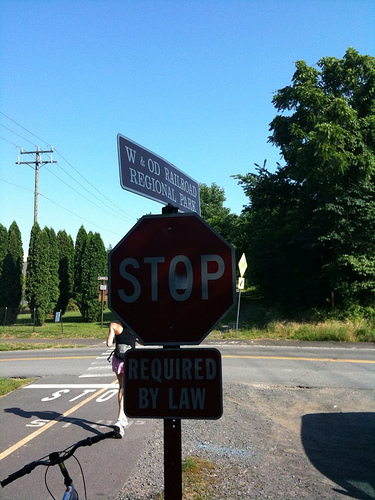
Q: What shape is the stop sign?
A: Octagon.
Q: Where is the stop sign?
A: Sidewalk.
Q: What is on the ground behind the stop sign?
A: Gravel.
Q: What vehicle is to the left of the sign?
A: Bicycle.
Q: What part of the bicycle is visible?
A: Handlebars.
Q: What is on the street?
A: Yellow lines.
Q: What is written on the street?
A: White words.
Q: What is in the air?
A: Power lines.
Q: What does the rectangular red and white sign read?
A: REQUIRED BY LAW.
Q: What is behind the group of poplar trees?
A: Telephone pole.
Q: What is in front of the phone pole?
A: A group of poplar trees.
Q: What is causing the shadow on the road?
A: Runner.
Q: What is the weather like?
A: Clear and sunny.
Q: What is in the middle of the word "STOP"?
A: A sticker.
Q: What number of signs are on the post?
A: 3.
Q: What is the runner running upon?
A: A paved path.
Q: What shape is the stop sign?
A: Octagon.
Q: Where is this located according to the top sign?
A: W & OD RAILROAD REGIONAL PARK.